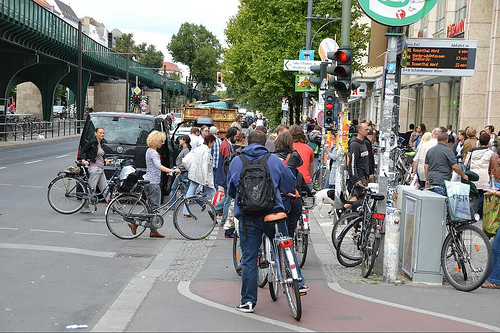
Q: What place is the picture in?
A: It is at the street.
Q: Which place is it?
A: It is a street.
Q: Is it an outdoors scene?
A: Yes, it is outdoors.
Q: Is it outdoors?
A: Yes, it is outdoors.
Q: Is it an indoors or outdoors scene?
A: It is outdoors.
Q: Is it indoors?
A: No, it is outdoors.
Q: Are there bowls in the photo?
A: No, there are no bowls.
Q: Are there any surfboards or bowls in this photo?
A: No, there are no bowls or surfboards.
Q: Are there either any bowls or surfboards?
A: No, there are no bowls or surfboards.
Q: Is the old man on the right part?
A: Yes, the man is on the right of the image.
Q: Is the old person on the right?
A: Yes, the man is on the right of the image.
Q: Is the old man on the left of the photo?
A: No, the man is on the right of the image.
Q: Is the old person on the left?
A: No, the man is on the right of the image.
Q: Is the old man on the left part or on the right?
A: The man is on the right of the image.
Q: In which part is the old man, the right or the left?
A: The man is on the right of the image.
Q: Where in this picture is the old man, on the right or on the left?
A: The man is on the right of the image.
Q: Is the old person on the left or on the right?
A: The man is on the right of the image.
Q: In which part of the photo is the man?
A: The man is on the right of the image.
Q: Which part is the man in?
A: The man is on the right of the image.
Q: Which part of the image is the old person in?
A: The man is on the right of the image.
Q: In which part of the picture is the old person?
A: The man is on the right of the image.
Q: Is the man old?
A: Yes, the man is old.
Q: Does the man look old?
A: Yes, the man is old.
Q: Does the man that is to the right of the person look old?
A: Yes, the man is old.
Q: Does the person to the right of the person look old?
A: Yes, the man is old.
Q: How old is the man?
A: The man is old.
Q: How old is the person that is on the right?
A: The man is old.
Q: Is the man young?
A: No, the man is old.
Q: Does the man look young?
A: No, the man is old.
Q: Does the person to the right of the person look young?
A: No, the man is old.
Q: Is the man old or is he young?
A: The man is old.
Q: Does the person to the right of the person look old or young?
A: The man is old.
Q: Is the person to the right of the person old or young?
A: The man is old.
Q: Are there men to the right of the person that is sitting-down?
A: Yes, there is a man to the right of the person.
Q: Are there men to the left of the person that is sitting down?
A: No, the man is to the right of the person.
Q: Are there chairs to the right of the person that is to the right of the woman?
A: No, there is a man to the right of the person.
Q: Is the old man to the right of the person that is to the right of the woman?
A: Yes, the man is to the right of the person.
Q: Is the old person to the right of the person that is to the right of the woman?
A: Yes, the man is to the right of the person.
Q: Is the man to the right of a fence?
A: No, the man is to the right of the person.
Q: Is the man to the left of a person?
A: No, the man is to the right of a person.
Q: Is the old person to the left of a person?
A: No, the man is to the right of a person.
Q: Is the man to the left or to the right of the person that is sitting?
A: The man is to the right of the person.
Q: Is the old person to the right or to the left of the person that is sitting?
A: The man is to the right of the person.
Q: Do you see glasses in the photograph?
A: No, there are no glasses.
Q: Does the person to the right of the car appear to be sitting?
A: Yes, the person is sitting.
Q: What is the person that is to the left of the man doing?
A: The person is sitting.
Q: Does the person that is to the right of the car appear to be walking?
A: No, the person is sitting.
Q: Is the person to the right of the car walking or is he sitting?
A: The person is sitting.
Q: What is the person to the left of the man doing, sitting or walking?
A: The person is sitting.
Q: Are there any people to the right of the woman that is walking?
A: Yes, there is a person to the right of the woman.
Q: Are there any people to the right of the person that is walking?
A: Yes, there is a person to the right of the woman.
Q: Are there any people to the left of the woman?
A: No, the person is to the right of the woman.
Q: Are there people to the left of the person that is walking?
A: No, the person is to the right of the woman.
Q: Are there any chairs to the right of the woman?
A: No, there is a person to the right of the woman.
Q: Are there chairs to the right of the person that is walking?
A: No, there is a person to the right of the woman.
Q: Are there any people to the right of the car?
A: Yes, there is a person to the right of the car.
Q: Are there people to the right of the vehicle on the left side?
A: Yes, there is a person to the right of the car.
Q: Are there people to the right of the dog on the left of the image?
A: Yes, there is a person to the right of the dog.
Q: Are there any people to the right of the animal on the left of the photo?
A: Yes, there is a person to the right of the dog.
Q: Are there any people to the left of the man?
A: Yes, there is a person to the left of the man.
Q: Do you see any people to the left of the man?
A: Yes, there is a person to the left of the man.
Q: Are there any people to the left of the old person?
A: Yes, there is a person to the left of the man.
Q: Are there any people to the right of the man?
A: No, the person is to the left of the man.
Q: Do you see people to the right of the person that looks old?
A: No, the person is to the left of the man.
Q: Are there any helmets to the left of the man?
A: No, there is a person to the left of the man.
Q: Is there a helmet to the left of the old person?
A: No, there is a person to the left of the man.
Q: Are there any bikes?
A: Yes, there is a bike.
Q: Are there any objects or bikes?
A: Yes, there is a bike.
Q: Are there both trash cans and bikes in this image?
A: No, there is a bike but no trash cans.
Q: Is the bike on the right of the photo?
A: Yes, the bike is on the right of the image.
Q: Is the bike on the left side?
A: No, the bike is on the right of the image.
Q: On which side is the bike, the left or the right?
A: The bike is on the right of the image.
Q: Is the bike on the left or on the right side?
A: The bike is on the right of the image.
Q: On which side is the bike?
A: The bike is on the right of the image.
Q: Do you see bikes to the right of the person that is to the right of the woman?
A: Yes, there is a bike to the right of the person.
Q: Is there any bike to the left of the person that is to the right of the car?
A: No, the bike is to the right of the person.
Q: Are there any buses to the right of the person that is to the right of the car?
A: No, there is a bike to the right of the person.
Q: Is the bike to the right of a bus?
A: No, the bike is to the right of the person.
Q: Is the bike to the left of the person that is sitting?
A: No, the bike is to the right of the person.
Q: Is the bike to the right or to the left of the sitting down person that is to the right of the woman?
A: The bike is to the right of the person.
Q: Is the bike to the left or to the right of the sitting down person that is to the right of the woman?
A: The bike is to the right of the person.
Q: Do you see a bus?
A: No, there are no buses.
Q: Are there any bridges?
A: Yes, there is a bridge.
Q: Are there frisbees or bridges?
A: Yes, there is a bridge.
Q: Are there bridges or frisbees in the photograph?
A: Yes, there is a bridge.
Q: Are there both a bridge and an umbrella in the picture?
A: No, there is a bridge but no umbrellas.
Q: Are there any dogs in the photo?
A: Yes, there is a dog.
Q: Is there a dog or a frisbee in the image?
A: Yes, there is a dog.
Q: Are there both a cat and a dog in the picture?
A: No, there is a dog but no cats.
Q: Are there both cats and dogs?
A: No, there is a dog but no cats.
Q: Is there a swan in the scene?
A: No, there are no swans.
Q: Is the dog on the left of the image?
A: Yes, the dog is on the left of the image.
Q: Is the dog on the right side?
A: No, the dog is on the left of the image.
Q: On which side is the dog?
A: The dog is on the left of the image.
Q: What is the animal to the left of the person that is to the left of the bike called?
A: The animal is a dog.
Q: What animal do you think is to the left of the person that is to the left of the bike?
A: The animal is a dog.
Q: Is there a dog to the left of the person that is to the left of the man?
A: Yes, there is a dog to the left of the person.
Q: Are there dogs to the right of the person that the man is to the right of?
A: No, the dog is to the left of the person.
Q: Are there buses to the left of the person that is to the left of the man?
A: No, there is a dog to the left of the person.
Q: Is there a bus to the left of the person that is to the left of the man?
A: No, there is a dog to the left of the person.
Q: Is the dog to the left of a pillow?
A: No, the dog is to the left of the person.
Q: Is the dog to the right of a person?
A: No, the dog is to the left of a person.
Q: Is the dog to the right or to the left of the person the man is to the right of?
A: The dog is to the left of the person.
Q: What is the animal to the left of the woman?
A: The animal is a dog.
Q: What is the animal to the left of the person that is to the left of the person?
A: The animal is a dog.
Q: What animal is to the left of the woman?
A: The animal is a dog.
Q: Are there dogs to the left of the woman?
A: Yes, there is a dog to the left of the woman.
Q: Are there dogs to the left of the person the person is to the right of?
A: Yes, there is a dog to the left of the woman.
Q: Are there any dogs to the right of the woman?
A: No, the dog is to the left of the woman.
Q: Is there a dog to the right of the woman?
A: No, the dog is to the left of the woman.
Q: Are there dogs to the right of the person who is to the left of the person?
A: No, the dog is to the left of the woman.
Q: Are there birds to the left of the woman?
A: No, there is a dog to the left of the woman.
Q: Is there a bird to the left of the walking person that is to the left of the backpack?
A: No, there is a dog to the left of the woman.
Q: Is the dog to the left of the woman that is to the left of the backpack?
A: Yes, the dog is to the left of the woman.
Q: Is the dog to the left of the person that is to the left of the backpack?
A: Yes, the dog is to the left of the woman.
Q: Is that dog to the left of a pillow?
A: No, the dog is to the left of the woman.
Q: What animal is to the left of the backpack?
A: The animal is a dog.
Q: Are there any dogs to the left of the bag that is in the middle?
A: Yes, there is a dog to the left of the backpack.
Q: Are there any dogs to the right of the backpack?
A: No, the dog is to the left of the backpack.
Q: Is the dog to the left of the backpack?
A: Yes, the dog is to the left of the backpack.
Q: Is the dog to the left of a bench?
A: No, the dog is to the left of the backpack.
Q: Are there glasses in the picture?
A: No, there are no glasses.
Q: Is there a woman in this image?
A: Yes, there is a woman.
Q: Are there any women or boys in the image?
A: Yes, there is a woman.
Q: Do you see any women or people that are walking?
A: Yes, the woman is walking.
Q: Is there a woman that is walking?
A: Yes, there is a woman that is walking.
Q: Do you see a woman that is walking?
A: Yes, there is a woman that is walking.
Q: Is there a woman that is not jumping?
A: Yes, there is a woman that is walking.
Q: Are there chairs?
A: No, there are no chairs.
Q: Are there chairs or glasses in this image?
A: No, there are no chairs or glasses.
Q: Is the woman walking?
A: Yes, the woman is walking.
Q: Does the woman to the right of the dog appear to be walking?
A: Yes, the woman is walking.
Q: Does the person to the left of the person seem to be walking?
A: Yes, the woman is walking.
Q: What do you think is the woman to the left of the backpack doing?
A: The woman is walking.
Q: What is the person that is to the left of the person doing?
A: The woman is walking.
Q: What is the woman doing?
A: The woman is walking.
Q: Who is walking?
A: The woman is walking.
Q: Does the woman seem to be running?
A: No, the woman is walking.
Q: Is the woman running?
A: No, the woman is walking.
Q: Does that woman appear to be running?
A: No, the woman is walking.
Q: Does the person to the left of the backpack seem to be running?
A: No, the woman is walking.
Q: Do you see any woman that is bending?
A: No, there is a woman but she is walking.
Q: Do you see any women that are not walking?
A: No, there is a woman but she is walking.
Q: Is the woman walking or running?
A: The woman is walking.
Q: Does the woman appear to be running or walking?
A: The woman is walking.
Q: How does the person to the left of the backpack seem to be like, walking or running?
A: The woman is walking.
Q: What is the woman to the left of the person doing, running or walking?
A: The woman is walking.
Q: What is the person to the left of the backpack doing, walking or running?
A: The woman is walking.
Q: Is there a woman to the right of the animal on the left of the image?
A: Yes, there is a woman to the right of the dog.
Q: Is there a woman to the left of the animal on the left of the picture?
A: No, the woman is to the right of the dog.